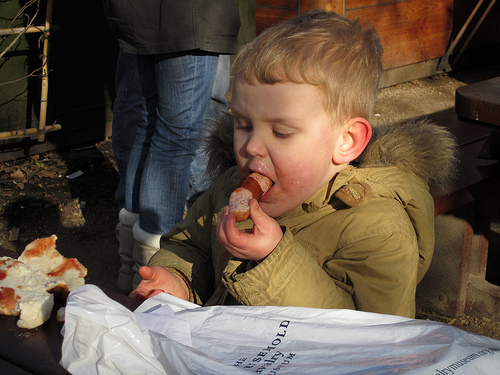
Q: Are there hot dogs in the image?
A: Yes, there is a hot dog.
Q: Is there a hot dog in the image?
A: Yes, there is a hot dog.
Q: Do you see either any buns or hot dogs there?
A: Yes, there is a hot dog.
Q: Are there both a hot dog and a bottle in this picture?
A: No, there is a hot dog but no bottles.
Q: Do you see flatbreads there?
A: No, there are no flatbreads.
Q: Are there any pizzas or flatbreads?
A: No, there are no flatbreads or pizzas.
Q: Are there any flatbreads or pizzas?
A: No, there are no flatbreads or pizzas.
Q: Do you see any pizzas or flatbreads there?
A: No, there are no flatbreads or pizzas.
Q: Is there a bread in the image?
A: Yes, there is a bread.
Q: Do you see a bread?
A: Yes, there is a bread.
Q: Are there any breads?
A: Yes, there is a bread.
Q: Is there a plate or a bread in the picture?
A: Yes, there is a bread.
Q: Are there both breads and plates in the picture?
A: No, there is a bread but no plates.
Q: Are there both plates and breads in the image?
A: No, there is a bread but no plates.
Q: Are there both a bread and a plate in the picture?
A: No, there is a bread but no plates.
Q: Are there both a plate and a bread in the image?
A: No, there is a bread but no plates.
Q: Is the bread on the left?
A: Yes, the bread is on the left of the image.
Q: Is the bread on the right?
A: No, the bread is on the left of the image.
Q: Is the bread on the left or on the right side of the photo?
A: The bread is on the left of the image.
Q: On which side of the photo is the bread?
A: The bread is on the left of the image.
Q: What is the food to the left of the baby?
A: The food is a bread.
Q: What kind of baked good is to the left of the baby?
A: The food is a bread.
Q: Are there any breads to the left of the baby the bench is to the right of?
A: Yes, there is a bread to the left of the baby.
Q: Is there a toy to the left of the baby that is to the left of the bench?
A: No, there is a bread to the left of the baby.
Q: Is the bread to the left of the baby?
A: Yes, the bread is to the left of the baby.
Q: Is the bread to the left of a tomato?
A: No, the bread is to the left of the baby.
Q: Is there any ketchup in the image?
A: Yes, there is ketchup.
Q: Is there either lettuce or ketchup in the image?
A: Yes, there is ketchup.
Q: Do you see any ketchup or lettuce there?
A: Yes, there is ketchup.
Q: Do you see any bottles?
A: No, there are no bottles.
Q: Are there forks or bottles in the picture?
A: No, there are no bottles or forks.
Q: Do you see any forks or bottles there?
A: No, there are no bottles or forks.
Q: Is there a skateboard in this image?
A: No, there are no skateboards.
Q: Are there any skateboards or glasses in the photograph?
A: No, there are no skateboards or glasses.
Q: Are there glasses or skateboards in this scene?
A: No, there are no skateboards or glasses.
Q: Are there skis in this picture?
A: No, there are no skis.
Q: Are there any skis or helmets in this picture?
A: No, there are no skis or helmets.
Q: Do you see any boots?
A: Yes, there are boots.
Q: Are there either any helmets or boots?
A: Yes, there are boots.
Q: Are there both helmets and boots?
A: No, there are boots but no helmets.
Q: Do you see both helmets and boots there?
A: No, there are boots but no helmets.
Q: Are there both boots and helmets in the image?
A: No, there are boots but no helmets.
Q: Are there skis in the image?
A: No, there are no skis.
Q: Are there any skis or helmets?
A: No, there are no skis or helmets.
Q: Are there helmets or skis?
A: No, there are no skis or helmets.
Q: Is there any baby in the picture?
A: Yes, there is a baby.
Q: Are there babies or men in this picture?
A: Yes, there is a baby.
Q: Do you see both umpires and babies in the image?
A: No, there is a baby but no umpires.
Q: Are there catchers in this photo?
A: No, there are no catchers.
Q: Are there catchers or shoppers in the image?
A: No, there are no catchers or shoppers.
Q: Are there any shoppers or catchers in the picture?
A: No, there are no catchers or shoppers.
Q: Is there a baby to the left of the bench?
A: Yes, there is a baby to the left of the bench.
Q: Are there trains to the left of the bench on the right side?
A: No, there is a baby to the left of the bench.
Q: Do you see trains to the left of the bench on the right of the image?
A: No, there is a baby to the left of the bench.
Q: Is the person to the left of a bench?
A: Yes, the baby is to the left of a bench.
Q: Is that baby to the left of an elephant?
A: No, the baby is to the left of a bench.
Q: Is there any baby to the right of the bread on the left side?
A: Yes, there is a baby to the right of the bread.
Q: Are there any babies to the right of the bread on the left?
A: Yes, there is a baby to the right of the bread.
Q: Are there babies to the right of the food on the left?
A: Yes, there is a baby to the right of the bread.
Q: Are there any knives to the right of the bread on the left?
A: No, there is a baby to the right of the bread.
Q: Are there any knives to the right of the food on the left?
A: No, there is a baby to the right of the bread.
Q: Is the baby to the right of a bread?
A: Yes, the baby is to the right of a bread.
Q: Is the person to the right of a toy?
A: No, the baby is to the right of a bread.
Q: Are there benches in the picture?
A: Yes, there is a bench.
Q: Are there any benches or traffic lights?
A: Yes, there is a bench.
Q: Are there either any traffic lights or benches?
A: Yes, there is a bench.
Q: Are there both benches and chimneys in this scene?
A: No, there is a bench but no chimneys.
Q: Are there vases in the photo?
A: No, there are no vases.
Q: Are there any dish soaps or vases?
A: No, there are no vases or dish soaps.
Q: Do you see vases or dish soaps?
A: No, there are no vases or dish soaps.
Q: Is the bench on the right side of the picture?
A: Yes, the bench is on the right of the image.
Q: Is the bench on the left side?
A: No, the bench is on the right of the image.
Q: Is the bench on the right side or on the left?
A: The bench is on the right of the image.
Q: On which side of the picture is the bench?
A: The bench is on the right of the image.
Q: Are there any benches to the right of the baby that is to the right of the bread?
A: Yes, there is a bench to the right of the baby.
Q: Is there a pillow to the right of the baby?
A: No, there is a bench to the right of the baby.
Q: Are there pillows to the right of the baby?
A: No, there is a bench to the right of the baby.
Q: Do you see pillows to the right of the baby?
A: No, there is a bench to the right of the baby.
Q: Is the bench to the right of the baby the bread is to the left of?
A: Yes, the bench is to the right of the baby.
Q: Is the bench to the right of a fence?
A: No, the bench is to the right of the baby.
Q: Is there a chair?
A: Yes, there is a chair.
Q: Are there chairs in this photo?
A: Yes, there is a chair.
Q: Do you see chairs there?
A: Yes, there is a chair.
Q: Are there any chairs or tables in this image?
A: Yes, there is a chair.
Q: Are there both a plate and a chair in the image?
A: No, there is a chair but no plates.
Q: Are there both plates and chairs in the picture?
A: No, there is a chair but no plates.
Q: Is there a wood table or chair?
A: Yes, there is a wood chair.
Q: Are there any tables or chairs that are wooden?
A: Yes, the chair is wooden.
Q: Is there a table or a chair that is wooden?
A: Yes, the chair is wooden.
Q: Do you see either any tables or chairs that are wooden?
A: Yes, the chair is wooden.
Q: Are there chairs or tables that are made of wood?
A: Yes, the chair is made of wood.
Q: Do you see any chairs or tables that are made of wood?
A: Yes, the chair is made of wood.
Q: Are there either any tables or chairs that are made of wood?
A: Yes, the chair is made of wood.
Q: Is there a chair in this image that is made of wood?
A: Yes, there is a chair that is made of wood.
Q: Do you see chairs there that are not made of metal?
A: Yes, there is a chair that is made of wood.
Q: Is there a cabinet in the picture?
A: No, there are no cabinets.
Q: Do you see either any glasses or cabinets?
A: No, there are no cabinets or glasses.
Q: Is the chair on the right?
A: Yes, the chair is on the right of the image.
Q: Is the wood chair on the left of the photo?
A: No, the chair is on the right of the image.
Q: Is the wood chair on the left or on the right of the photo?
A: The chair is on the right of the image.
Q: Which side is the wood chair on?
A: The chair is on the right of the image.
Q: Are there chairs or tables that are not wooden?
A: No, there is a chair but it is wooden.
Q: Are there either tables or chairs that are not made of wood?
A: No, there is a chair but it is made of wood.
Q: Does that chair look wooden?
A: Yes, the chair is wooden.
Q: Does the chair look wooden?
A: Yes, the chair is wooden.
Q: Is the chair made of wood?
A: Yes, the chair is made of wood.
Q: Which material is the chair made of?
A: The chair is made of wood.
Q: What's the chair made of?
A: The chair is made of wood.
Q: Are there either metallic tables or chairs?
A: No, there is a chair but it is wooden.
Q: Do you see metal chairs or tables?
A: No, there is a chair but it is wooden.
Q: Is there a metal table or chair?
A: No, there is a chair but it is wooden.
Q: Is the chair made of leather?
A: No, the chair is made of wood.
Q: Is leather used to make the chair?
A: No, the chair is made of wood.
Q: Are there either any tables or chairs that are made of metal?
A: No, there is a chair but it is made of wood.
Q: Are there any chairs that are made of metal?
A: No, there is a chair but it is made of wood.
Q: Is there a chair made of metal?
A: No, there is a chair but it is made of wood.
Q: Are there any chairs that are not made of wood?
A: No, there is a chair but it is made of wood.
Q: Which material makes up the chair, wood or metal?
A: The chair is made of wood.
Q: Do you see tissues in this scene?
A: No, there are no tissues.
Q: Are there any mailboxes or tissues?
A: No, there are no tissues or mailboxes.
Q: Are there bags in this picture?
A: Yes, there is a bag.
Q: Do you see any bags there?
A: Yes, there is a bag.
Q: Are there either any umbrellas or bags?
A: Yes, there is a bag.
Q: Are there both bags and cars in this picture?
A: No, there is a bag but no cars.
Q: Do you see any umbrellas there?
A: No, there are no umbrellas.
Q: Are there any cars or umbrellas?
A: No, there are no umbrellas or cars.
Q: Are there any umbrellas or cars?
A: No, there are no umbrellas or cars.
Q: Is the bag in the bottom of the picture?
A: Yes, the bag is in the bottom of the image.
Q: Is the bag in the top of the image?
A: No, the bag is in the bottom of the image.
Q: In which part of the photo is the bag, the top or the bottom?
A: The bag is in the bottom of the image.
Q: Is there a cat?
A: No, there are no cats.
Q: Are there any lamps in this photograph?
A: No, there are no lamps.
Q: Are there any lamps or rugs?
A: No, there are no lamps or rugs.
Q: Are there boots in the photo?
A: Yes, there are boots.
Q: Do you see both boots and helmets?
A: No, there are boots but no helmets.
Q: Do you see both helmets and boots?
A: No, there are boots but no helmets.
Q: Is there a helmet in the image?
A: No, there are no helmets.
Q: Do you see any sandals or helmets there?
A: No, there are no helmets or sandals.